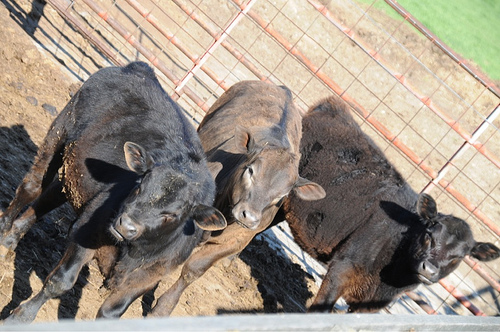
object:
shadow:
[252, 238, 306, 305]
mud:
[53, 157, 84, 207]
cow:
[142, 80, 325, 318]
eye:
[243, 164, 257, 179]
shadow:
[15, 5, 63, 33]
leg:
[309, 261, 354, 310]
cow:
[282, 95, 499, 313]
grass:
[432, 9, 485, 41]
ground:
[200, 265, 245, 311]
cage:
[0, 0, 499, 322]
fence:
[8, 2, 498, 329]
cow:
[10, 60, 228, 330]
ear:
[410, 190, 442, 224]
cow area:
[0, 61, 499, 332]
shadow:
[2, 117, 29, 182]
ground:
[5, 67, 61, 106]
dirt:
[207, 272, 293, 307]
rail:
[26, 7, 478, 80]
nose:
[110, 213, 136, 239]